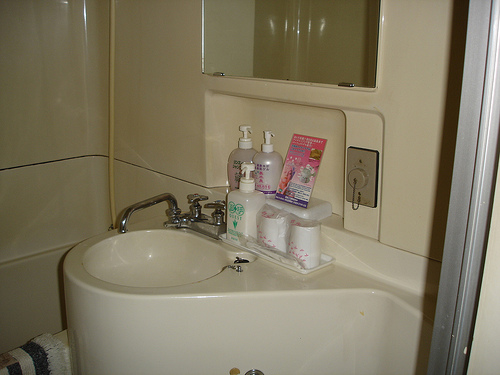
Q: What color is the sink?
A: White.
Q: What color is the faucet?
A: Silver.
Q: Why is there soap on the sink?
A: For hand washing.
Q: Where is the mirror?
A: Above the sink.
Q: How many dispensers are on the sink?
A: 3.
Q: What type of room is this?
A: A bathroom.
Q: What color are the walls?
A: Beige.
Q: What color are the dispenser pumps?
A: White.